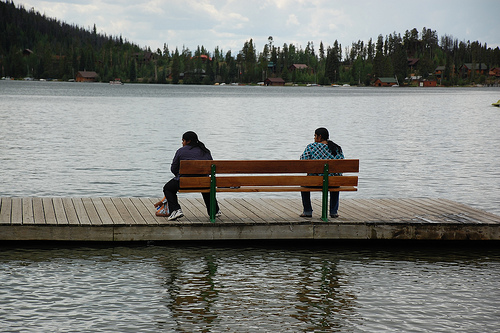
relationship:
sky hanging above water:
[4, 0, 484, 55] [2, 77, 483, 331]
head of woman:
[180, 129, 200, 149] [163, 129, 221, 219]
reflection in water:
[156, 250, 360, 329] [2, 77, 483, 331]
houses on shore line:
[196, 22, 384, 105] [116, 17, 373, 126]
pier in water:
[4, 184, 498, 260] [6, 109, 496, 325]